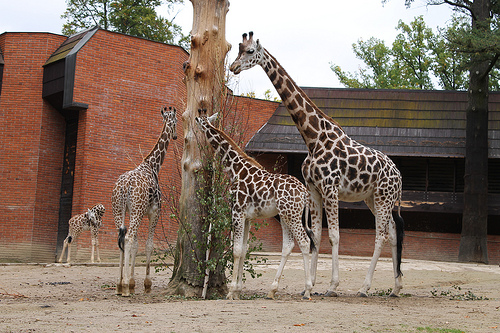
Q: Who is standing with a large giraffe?
A: A young giraffe.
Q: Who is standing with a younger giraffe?
A: A large giraffe.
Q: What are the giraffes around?
A: Tree with branches and limbs cut off.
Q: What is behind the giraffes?
A: Another tree with lower branches and limbs cut off.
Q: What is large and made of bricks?
A: A building.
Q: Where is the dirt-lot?
A: Giraffe's area.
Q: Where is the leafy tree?
A: Outside the pen.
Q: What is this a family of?
A: Giraffes.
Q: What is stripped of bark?
A: A tree.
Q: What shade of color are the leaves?
A: Green.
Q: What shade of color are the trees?
A: Green.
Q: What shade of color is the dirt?
A: Brown.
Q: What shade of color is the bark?
A: Brown.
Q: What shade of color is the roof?
A: Brown.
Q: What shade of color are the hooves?
A: Brown.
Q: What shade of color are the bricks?
A: Red.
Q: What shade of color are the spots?
A: Brown.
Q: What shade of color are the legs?
A: Brown.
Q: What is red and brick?
A: The wall.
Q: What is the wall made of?
A: Bricks.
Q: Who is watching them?
A: People.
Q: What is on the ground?
A: Dirt.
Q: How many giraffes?
A: 4.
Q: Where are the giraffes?
A: Next to the tree.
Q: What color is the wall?
A: Red.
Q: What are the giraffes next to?
A: Tree.